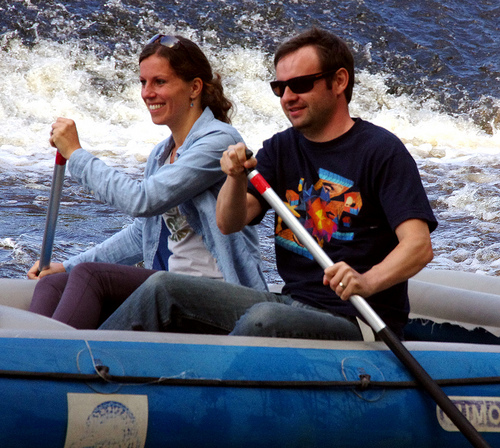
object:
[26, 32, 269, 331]
woman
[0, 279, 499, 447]
boat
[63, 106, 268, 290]
blazer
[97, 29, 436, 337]
man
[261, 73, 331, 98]
sunglasses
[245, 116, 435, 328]
tshirt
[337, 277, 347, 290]
ring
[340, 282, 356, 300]
finger